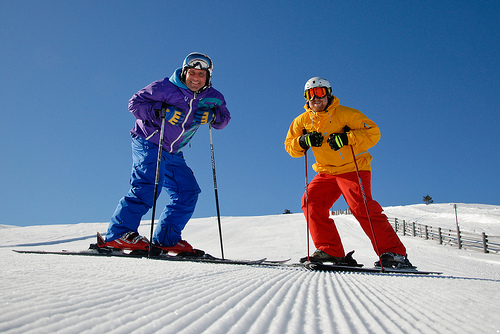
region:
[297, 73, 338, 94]
Man wearing protective helmet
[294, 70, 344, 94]
Man's helmet is white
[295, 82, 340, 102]
Man wearing protective goggles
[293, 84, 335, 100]
Man's goggles have orange lens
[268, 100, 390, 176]
Man wearing yellow ski jacket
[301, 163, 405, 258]
Man wearing orange ski pants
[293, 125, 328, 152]
Man wearing black glove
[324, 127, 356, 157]
Man wearing black glove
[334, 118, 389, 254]
Man holding ski pole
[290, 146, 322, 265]
Man holding ski pole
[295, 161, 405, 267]
red ski pants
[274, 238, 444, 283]
skiing boots and skis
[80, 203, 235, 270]
red ski boots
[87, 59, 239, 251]
blue ski suit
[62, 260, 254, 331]
fresh plowed snow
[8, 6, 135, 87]
crystal clear blue sky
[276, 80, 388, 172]
a yellow ski jacket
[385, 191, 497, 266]
a wooden fence around the ski track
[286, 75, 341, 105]
a skier wearing skiing goggles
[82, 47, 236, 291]
a man out skiing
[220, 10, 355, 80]
The sky is blue and clear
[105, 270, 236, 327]
The snow is white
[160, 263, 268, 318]
The snow has tracks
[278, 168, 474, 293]
The man has red snow pants on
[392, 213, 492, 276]
The fence is wooden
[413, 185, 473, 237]
The tree is in the back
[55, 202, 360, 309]
The men are skiing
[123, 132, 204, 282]
The man's snow pants are blue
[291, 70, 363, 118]
The man has googles on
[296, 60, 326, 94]
The man has a helmet on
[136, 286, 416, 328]
TRACKS IN THE SNOW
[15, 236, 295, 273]
A PAIR OF SKIS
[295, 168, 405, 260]
A PAIR OF RED SNOW PANTS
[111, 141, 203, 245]
A PAIR OF BLUE SNOW PANTS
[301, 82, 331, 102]
A PAIR OF SKI GOGGLES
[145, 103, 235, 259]
A PAIR OF SKI POLES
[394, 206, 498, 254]
A WOODEN FENCE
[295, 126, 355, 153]
BLACK AND YELLOW GLOVES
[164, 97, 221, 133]
BLUE AND YELLOW GLOVES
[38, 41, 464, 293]
A PHOTO OF TWO SKIERS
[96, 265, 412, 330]
ski marks on the snow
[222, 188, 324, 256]
hill covered in snow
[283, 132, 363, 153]
yellow stripes on his gloves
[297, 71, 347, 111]
skier is wearing his goggles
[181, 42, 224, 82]
skier's goggles on his forehead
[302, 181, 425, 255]
ski pants are red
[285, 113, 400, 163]
ski jacket is bright yellow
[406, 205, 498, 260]
fence along the hill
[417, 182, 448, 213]
tree at the top of hill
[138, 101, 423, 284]
ski poles in the snow